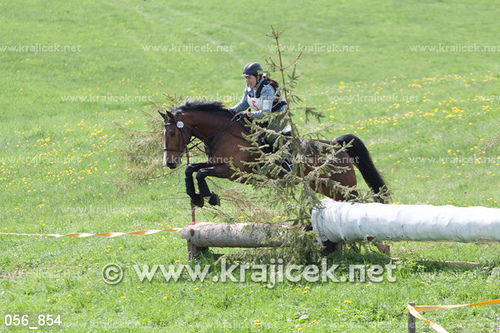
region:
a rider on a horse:
[156, 62, 403, 211]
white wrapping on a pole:
[310, 193, 499, 260]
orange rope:
[401, 291, 497, 330]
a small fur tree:
[224, 25, 399, 276]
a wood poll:
[181, 218, 313, 275]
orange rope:
[0, 224, 190, 247]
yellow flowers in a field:
[8, 118, 135, 196]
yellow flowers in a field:
[326, 68, 497, 178]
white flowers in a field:
[8, 39, 493, 71]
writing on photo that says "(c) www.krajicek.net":
[92, 258, 409, 284]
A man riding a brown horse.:
[218, 52, 294, 130]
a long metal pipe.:
[305, 191, 498, 251]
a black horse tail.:
[333, 129, 395, 207]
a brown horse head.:
[154, 96, 224, 172]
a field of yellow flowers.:
[0, 69, 495, 219]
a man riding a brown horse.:
[213, 57, 297, 133]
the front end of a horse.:
[161, 137, 245, 214]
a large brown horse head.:
[142, 80, 221, 192]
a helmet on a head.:
[238, 57, 270, 87]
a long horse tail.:
[334, 130, 404, 210]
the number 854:
[37, 312, 62, 329]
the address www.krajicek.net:
[134, 260, 399, 285]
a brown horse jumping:
[150, 102, 386, 208]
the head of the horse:
[158, 108, 191, 165]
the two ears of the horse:
[158, 109, 175, 122]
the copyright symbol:
[103, 264, 123, 285]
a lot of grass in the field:
[20, 4, 393, 51]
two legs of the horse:
[183, 162, 228, 209]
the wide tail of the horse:
[341, 138, 391, 197]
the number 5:
[248, 98, 260, 112]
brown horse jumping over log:
[153, 104, 375, 196]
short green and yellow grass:
[14, 6, 44, 50]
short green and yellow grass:
[30, 95, 100, 167]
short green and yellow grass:
[44, 178, 102, 219]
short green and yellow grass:
[21, 249, 69, 290]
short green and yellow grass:
[360, 41, 441, 108]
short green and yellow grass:
[397, 119, 448, 137]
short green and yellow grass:
[393, 116, 457, 174]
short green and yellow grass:
[341, 5, 389, 62]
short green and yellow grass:
[126, 35, 183, 57]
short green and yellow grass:
[30, 13, 82, 51]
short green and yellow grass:
[4, 50, 41, 97]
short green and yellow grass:
[54, 59, 95, 117]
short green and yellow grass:
[39, 260, 75, 291]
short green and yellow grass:
[186, 301, 229, 326]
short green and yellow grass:
[108, 20, 183, 83]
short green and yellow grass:
[310, 18, 356, 68]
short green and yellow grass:
[378, 23, 437, 66]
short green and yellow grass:
[388, 56, 456, 116]